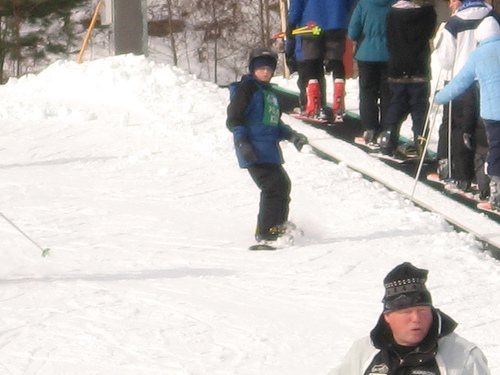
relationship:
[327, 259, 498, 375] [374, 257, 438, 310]
man wearing hat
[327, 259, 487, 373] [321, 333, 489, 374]
man wearing jacket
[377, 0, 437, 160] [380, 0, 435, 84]
person wearing hoody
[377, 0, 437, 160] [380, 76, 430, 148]
person wearing pants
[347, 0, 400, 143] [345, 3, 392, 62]
person wearing jacket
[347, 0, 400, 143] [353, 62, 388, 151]
person wearing pants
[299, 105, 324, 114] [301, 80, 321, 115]
foot wearing boot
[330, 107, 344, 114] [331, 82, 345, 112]
foot wearing boot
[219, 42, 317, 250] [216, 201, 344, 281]
boy on a snowboard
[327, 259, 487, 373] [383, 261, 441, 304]
man wearing hat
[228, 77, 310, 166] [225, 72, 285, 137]
jacket with sleeves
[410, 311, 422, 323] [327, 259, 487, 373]
nose of man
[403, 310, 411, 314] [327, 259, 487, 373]
eye of man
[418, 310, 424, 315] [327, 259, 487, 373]
eye of man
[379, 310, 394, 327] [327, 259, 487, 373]
ear of man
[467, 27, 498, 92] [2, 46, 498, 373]
boy snowboarding in snow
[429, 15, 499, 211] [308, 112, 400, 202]
person in line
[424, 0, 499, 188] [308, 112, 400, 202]
person in line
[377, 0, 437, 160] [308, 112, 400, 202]
person in line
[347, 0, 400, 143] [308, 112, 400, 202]
person in line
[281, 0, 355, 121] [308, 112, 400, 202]
person in line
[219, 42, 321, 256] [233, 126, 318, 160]
boy wearing gloves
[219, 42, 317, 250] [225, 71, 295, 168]
boy wearing jacket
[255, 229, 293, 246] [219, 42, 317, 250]
skate on boy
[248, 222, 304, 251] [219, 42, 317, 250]
skate on boy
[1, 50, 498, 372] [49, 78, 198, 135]
hill covered in snow